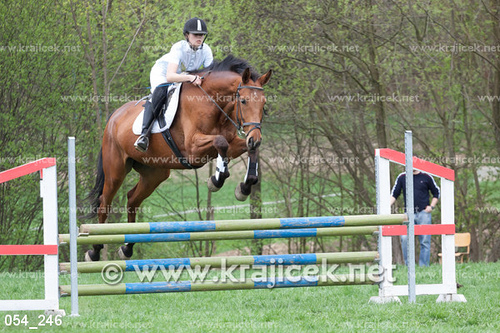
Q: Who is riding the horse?
A: Jockey.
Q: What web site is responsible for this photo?
A: Www.krajicek.net.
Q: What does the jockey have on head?
A: Helmet.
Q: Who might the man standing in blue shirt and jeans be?
A: Horse's trainer.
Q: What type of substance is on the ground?
A: Grass.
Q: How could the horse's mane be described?
A: Black.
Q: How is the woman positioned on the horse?
A: Leaning forward.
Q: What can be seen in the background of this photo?
A: Slender trees.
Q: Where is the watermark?
A: On website.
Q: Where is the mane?
A: On horse.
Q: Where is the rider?
A: On horse.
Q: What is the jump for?
A: Horses.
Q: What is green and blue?
A: Pylons.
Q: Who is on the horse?
A: Jockey.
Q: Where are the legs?
A: On horse.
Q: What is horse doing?
A: Jumping.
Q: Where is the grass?
A: On the ground.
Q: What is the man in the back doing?
A: Man watching horse and jockey.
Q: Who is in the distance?
A: Man with blue top and jeans at a distance.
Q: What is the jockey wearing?
A: Female jockey in light colored clothes and black boots.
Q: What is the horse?
A: Brown horse with black hair.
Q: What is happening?
A: Woman riding a horse wearing a black hat.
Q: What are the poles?
A: Green and blue poles.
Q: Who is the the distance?
A: A man standing in the back.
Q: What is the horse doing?
A: Horse about to jump over a gate.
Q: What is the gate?
A: Red and white gate.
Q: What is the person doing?
A: Riding a horse.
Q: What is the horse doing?
A: Jumping.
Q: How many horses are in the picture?
A: One.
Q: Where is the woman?
A: On the horse.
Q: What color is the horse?
A: Brown.